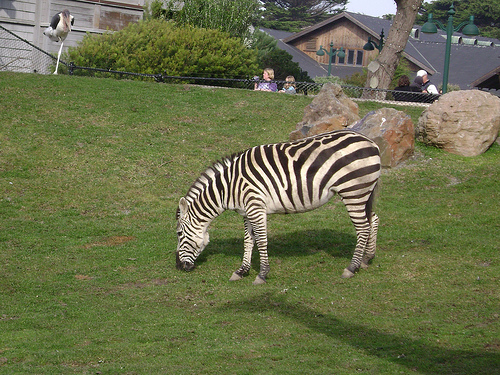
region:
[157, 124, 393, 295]
zebra grazing in the grass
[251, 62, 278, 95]
woman with a camera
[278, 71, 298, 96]
girl walking with a woman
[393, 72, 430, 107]
people wearing black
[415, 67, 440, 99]
man with a white cap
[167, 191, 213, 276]
head of a zebra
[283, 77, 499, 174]
three boulders in the grass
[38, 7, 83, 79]
large bird on one leg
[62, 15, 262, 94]
large green bush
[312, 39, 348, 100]
green metal lamp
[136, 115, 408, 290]
Black and white zebra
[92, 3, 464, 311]
Zebra at the zoo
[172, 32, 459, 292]
People walking at the zoo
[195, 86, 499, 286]
Rocks behind a zebra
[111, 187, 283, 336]
Zebra eating grass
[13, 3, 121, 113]
Stork walking on one leg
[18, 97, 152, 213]
Green grass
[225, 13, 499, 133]
Brown building with people in front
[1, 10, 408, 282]
Bird and a zebra walking on grass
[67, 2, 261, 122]
Green bushes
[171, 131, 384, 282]
zebra eating grass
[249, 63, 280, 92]
woman taking video or pictures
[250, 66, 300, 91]
woman and child watching ostrich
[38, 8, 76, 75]
ostrich standing on one leg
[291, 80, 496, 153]
rocks behind zebra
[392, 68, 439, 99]
people talking by the tree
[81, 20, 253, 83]
bush on other side of the enclosure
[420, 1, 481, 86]
lights on a pole outside the fence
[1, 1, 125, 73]
whit building on the other side of the fence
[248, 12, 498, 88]
barn on other side of fence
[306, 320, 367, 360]
part of some grass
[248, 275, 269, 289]
part of a zebra hoof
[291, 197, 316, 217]
stomach of a zebra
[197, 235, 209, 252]
jaw of a zebra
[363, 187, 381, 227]
tail of a zebra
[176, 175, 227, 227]
neck of a zebra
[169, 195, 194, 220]
ear of a zebra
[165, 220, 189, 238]
eye of a zebra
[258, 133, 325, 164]
back of a zebra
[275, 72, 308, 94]
edge of a fence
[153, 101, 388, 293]
gray and white zebra in enclosure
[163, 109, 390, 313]
gray and white zebra grazing on green grass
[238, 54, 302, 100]
tourists taking pictures with camera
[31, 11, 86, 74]
brown, black and white bird standing on one leg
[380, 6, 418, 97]
brown tree near zebra enclosure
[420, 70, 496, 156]
large brown rock in zebra enclosure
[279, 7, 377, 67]
brown and black structure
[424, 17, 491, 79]
brown and black structure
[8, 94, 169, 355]
green grass in zebra enclosure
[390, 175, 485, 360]
green grass in zebra enclosure